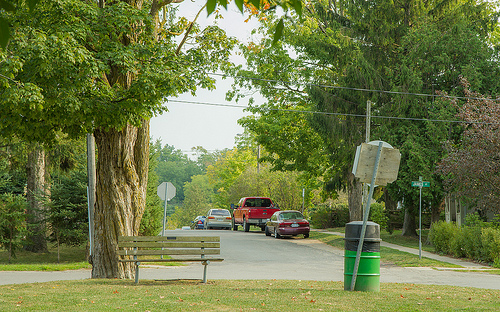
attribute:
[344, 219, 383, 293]
trash can — green, black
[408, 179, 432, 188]
sign — green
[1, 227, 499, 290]
road — concrete, t-shaped, gray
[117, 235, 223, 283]
bench — wooden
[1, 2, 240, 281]
tree — tall, large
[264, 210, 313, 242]
car — purple, red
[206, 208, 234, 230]
car — tan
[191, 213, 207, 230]
car — green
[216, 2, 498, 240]
trees — tall, large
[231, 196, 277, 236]
truck — red, orange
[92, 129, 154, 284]
trunk — thick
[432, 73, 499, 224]
tree — purple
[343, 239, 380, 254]
bag — black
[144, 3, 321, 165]
sky — gray, cloudy